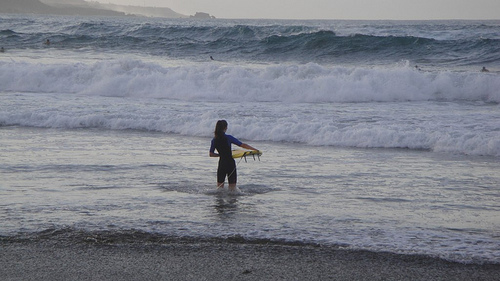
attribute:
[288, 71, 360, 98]
waves — large, white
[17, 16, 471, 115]
waves — large, white, crashing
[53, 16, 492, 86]
waves — crashing, large, white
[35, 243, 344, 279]
beach — sandy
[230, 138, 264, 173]
surfboard — yellow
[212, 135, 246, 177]
wetsuit — black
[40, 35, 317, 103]
wave — water, foamy